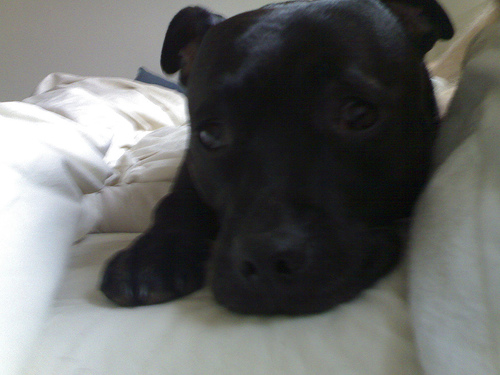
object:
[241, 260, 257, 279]
nostril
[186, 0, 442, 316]
face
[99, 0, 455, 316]
dog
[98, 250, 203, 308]
paw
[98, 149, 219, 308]
foot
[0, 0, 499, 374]
bed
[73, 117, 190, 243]
crease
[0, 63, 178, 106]
edge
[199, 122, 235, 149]
eye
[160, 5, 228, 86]
ear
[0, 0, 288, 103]
wall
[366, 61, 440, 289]
side of face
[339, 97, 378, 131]
eye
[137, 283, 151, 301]
nail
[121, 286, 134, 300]
nail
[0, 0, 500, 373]
bedding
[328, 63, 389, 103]
puppy eyebrow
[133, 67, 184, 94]
pillow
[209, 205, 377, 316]
muzzle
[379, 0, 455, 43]
ear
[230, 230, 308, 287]
nose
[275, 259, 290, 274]
nostril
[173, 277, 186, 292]
nail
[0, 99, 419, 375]
sheet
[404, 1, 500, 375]
pillow